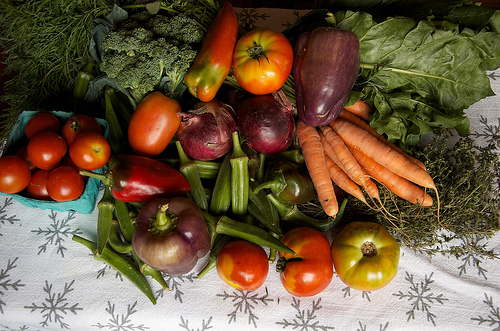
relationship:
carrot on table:
[323, 124, 367, 172] [3, 9, 500, 326]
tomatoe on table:
[277, 228, 331, 292] [3, 9, 500, 326]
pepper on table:
[262, 162, 323, 207] [3, 9, 500, 326]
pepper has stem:
[262, 162, 323, 207] [251, 175, 288, 198]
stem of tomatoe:
[273, 251, 288, 271] [277, 228, 331, 292]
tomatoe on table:
[336, 222, 404, 290] [3, 9, 500, 326]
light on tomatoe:
[365, 266, 385, 283] [336, 222, 404, 290]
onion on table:
[179, 100, 235, 161] [3, 9, 500, 326]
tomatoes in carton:
[0, 112, 99, 191] [8, 109, 111, 210]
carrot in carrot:
[295, 119, 341, 222] [295, 119, 341, 222]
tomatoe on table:
[132, 91, 185, 157] [3, 9, 500, 326]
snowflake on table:
[34, 278, 83, 327] [3, 9, 500, 326]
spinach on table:
[351, 14, 489, 110] [3, 9, 500, 326]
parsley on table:
[434, 137, 492, 190] [3, 9, 500, 326]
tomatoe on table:
[214, 237, 270, 292] [3, 9, 500, 326]